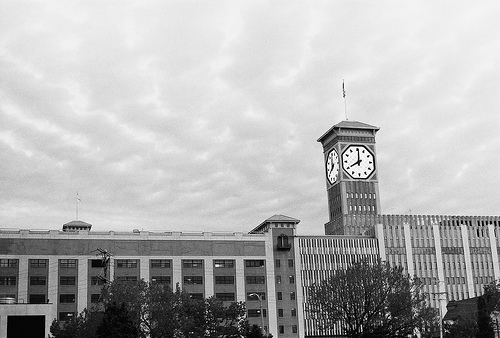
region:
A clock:
[324, 98, 424, 282]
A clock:
[292, 50, 467, 222]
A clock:
[285, 94, 386, 249]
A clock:
[325, 132, 416, 206]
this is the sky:
[105, 85, 195, 157]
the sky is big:
[35, 58, 260, 202]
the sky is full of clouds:
[35, 46, 250, 142]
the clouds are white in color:
[53, 89, 178, 181]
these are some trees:
[41, 267, 436, 331]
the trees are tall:
[43, 267, 438, 333]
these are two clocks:
[321, 147, 379, 182]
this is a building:
[16, 119, 495, 322]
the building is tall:
[314, 113, 413, 325]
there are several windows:
[151, 259, 270, 284]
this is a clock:
[343, 156, 375, 176]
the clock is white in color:
[351, 152, 356, 157]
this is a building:
[423, 214, 485, 263]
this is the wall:
[128, 237, 223, 252]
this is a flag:
[70, 186, 86, 215]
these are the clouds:
[97, 60, 268, 201]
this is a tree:
[331, 280, 407, 332]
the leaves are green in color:
[161, 287, 189, 306]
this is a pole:
[257, 295, 272, 332]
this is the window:
[219, 273, 231, 279]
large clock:
[315, 145, 390, 191]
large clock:
[317, 123, 397, 216]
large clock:
[328, 127, 379, 184]